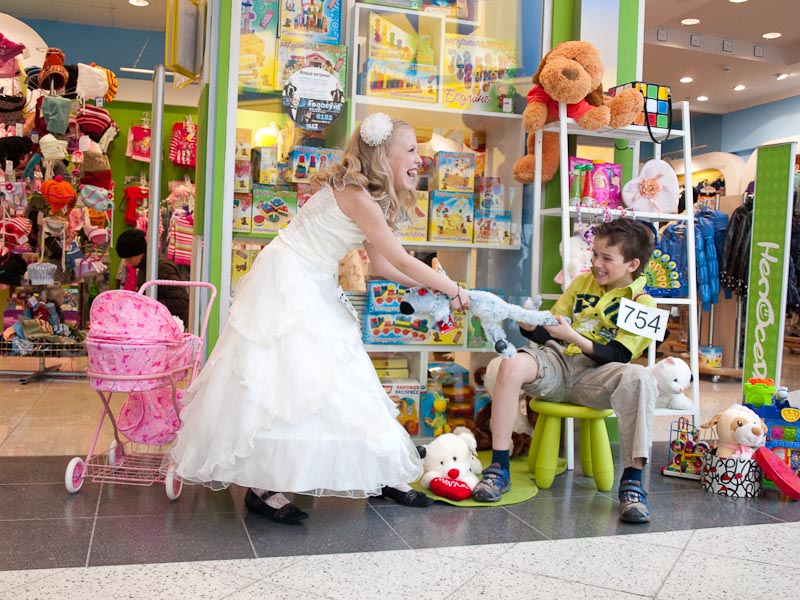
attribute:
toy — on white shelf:
[620, 75, 673, 128]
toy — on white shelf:
[517, 37, 645, 138]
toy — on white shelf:
[608, 80, 677, 136]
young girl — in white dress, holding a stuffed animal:
[158, 112, 457, 523]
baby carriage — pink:
[62, 270, 219, 502]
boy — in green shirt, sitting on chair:
[478, 219, 671, 525]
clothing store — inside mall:
[2, 7, 192, 383]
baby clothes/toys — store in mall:
[2, 7, 643, 433]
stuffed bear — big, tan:
[518, 37, 648, 134]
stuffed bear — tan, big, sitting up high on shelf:
[511, 34, 644, 186]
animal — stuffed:
[458, 263, 560, 353]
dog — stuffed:
[516, 40, 642, 186]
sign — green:
[737, 140, 796, 393]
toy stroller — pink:
[65, 278, 216, 494]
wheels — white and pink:
[61, 444, 186, 497]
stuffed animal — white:
[413, 424, 482, 502]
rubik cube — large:
[615, 83, 667, 128]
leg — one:
[593, 421, 613, 493]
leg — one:
[577, 406, 598, 477]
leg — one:
[533, 415, 563, 493]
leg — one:
[520, 418, 540, 477]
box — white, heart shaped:
[622, 157, 684, 216]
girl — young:
[178, 112, 470, 525]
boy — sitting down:
[472, 214, 649, 525]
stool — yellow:
[528, 399, 616, 492]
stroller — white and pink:
[65, 281, 220, 497]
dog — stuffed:
[529, 40, 604, 105]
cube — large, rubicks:
[608, 82, 669, 127]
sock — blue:
[493, 445, 510, 461]